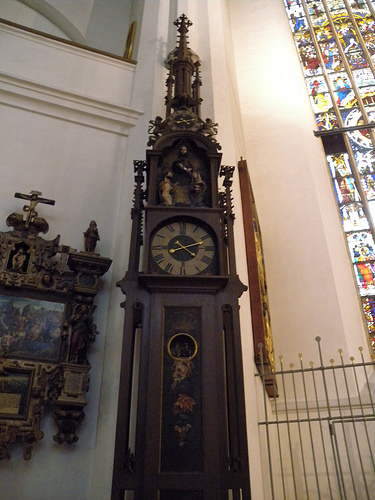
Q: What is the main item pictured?
A: Floor clock.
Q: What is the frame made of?
A: Wood.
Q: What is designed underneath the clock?
A: A rectangle.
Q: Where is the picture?
A: On the left side of the clock.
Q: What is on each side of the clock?
A: A rectangular slot.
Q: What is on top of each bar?
A: A metal bar designed with balls.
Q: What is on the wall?
A: Religious painting and frame.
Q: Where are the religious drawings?
A: In front of a clock.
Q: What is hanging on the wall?
A: A framed picture.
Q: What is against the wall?
A: An ornate decoration.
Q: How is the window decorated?
A: Stained glass.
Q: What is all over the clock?
A: Religious images.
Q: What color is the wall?
A: White.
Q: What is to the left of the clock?
A: Religious artwork.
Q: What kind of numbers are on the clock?
A: Roman numeral.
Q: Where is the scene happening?
A: A church.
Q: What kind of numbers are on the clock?
A: Roman.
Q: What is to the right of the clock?
A: A window.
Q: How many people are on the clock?
A: Three.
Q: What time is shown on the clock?
A: 4:10.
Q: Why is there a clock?
A: To tell time.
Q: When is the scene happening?
A: Daytime.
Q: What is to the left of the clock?
A: A painting.